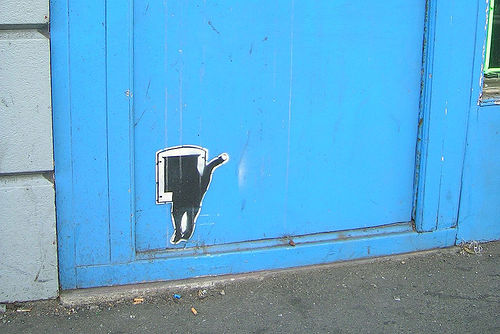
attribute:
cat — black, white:
[167, 150, 231, 247]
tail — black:
[201, 152, 230, 192]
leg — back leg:
[182, 206, 201, 243]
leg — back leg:
[169, 201, 184, 244]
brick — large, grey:
[0, 1, 52, 34]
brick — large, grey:
[0, 26, 57, 179]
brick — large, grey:
[0, 173, 65, 308]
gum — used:
[172, 292, 183, 297]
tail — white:
[213, 148, 231, 167]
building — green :
[20, 15, 495, 330]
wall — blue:
[31, 0, 475, 297]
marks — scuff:
[32, 267, 53, 284]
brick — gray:
[1, 175, 59, 305]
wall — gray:
[1, 7, 63, 309]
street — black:
[226, 283, 498, 316]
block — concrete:
[3, 28, 55, 174]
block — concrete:
[2, 175, 59, 301]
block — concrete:
[2, 1, 47, 29]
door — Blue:
[73, 100, 288, 331]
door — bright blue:
[278, 50, 452, 186]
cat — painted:
[168, 152, 228, 242]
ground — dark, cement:
[244, 256, 424, 330]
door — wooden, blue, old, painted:
[45, 3, 483, 289]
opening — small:
[156, 147, 205, 205]